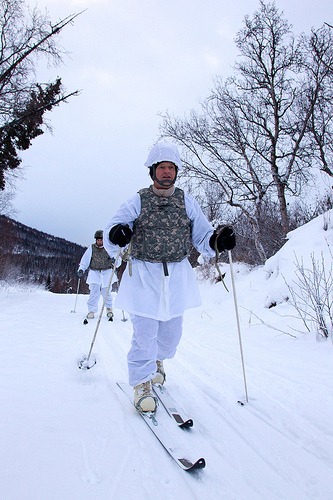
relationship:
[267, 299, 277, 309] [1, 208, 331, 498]
hole in snow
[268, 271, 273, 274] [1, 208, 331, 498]
hole in snow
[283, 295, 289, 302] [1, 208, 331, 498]
hole in snow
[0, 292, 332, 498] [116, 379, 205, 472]
snow edge of ski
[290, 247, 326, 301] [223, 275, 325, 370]
branches coming out snow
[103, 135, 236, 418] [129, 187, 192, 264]
man wearing camo vest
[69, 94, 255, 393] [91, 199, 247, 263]
man wearing gloves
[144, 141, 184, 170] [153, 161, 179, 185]
cover strapped to face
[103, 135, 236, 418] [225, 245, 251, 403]
man holding pole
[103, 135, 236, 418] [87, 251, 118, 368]
man holding pole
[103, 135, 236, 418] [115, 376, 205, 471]
man standing on skis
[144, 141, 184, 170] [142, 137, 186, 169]
cover over helmet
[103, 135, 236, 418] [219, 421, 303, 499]
man skiing on trail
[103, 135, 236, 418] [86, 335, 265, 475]
man on path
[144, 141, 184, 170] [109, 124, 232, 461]
cover of soldier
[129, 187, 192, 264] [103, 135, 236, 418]
camo vest of man